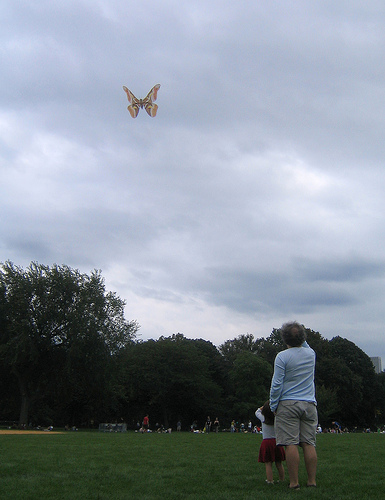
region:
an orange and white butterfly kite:
[120, 83, 164, 120]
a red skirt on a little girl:
[256, 436, 289, 467]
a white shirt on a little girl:
[253, 408, 279, 440]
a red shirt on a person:
[141, 416, 151, 426]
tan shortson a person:
[272, 399, 320, 448]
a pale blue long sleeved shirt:
[266, 338, 316, 411]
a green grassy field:
[1, 428, 384, 499]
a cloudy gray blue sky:
[1, 1, 383, 372]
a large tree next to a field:
[0, 262, 126, 433]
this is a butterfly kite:
[92, 55, 189, 147]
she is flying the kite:
[246, 383, 301, 484]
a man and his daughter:
[225, 281, 357, 496]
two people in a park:
[220, 263, 378, 496]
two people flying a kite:
[201, 277, 379, 497]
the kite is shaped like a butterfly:
[78, 53, 222, 164]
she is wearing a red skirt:
[236, 386, 299, 478]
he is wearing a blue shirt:
[269, 290, 325, 429]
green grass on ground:
[18, 435, 49, 455]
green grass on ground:
[63, 435, 89, 457]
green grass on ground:
[104, 442, 128, 458]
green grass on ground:
[129, 458, 147, 472]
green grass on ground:
[165, 438, 188, 456]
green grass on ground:
[189, 456, 218, 483]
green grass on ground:
[235, 434, 252, 453]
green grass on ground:
[338, 439, 357, 459]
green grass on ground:
[336, 467, 357, 491]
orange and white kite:
[108, 87, 163, 116]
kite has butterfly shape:
[108, 87, 164, 125]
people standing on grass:
[250, 328, 328, 495]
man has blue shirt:
[268, 352, 313, 412]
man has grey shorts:
[271, 405, 310, 443]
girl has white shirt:
[243, 403, 290, 445]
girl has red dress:
[259, 444, 289, 461]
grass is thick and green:
[101, 444, 228, 481]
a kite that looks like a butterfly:
[118, 75, 167, 121]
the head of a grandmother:
[275, 320, 301, 342]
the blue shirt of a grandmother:
[272, 339, 317, 411]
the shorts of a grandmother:
[275, 393, 316, 450]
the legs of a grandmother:
[283, 439, 320, 479]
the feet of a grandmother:
[275, 474, 316, 491]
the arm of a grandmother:
[262, 343, 291, 406]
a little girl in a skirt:
[249, 400, 277, 480]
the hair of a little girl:
[255, 401, 272, 423]